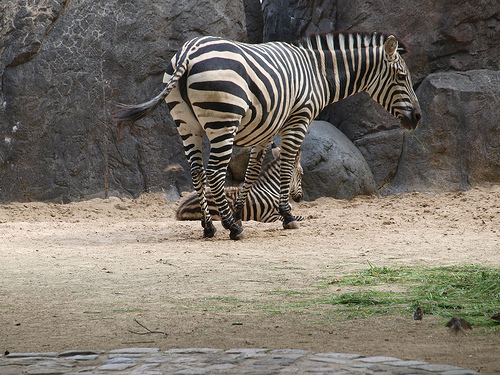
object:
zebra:
[111, 29, 424, 240]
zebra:
[174, 147, 305, 224]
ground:
[3, 193, 497, 372]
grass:
[321, 261, 500, 319]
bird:
[414, 306, 424, 320]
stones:
[1, 346, 476, 374]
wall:
[0, 1, 500, 198]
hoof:
[229, 228, 247, 240]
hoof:
[202, 229, 219, 238]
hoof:
[283, 218, 300, 229]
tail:
[110, 56, 195, 129]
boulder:
[423, 76, 499, 185]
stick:
[127, 319, 172, 344]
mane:
[292, 27, 408, 56]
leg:
[190, 90, 253, 229]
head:
[363, 33, 422, 131]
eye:
[398, 73, 407, 81]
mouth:
[401, 117, 419, 130]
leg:
[162, 95, 213, 226]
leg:
[277, 106, 313, 221]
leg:
[231, 143, 274, 218]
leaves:
[232, 322, 243, 326]